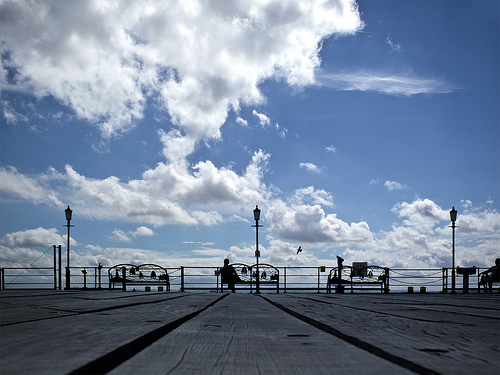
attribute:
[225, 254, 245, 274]
man — sitting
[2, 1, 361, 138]
cloud — big, bright, white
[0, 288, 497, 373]
floor — old, brown, wooden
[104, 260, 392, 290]
benches — spare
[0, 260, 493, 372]
dock — nice, big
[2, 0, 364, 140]
clouds — white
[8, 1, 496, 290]
sky — bright, clear, blue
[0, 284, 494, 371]
platform — wooden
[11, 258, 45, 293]
railing — pole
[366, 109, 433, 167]
sky — blue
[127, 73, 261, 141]
clouds — puffy, white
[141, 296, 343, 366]
boards — wooden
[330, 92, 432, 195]
sky — blue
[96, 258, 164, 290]
design — intricate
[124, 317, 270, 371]
planks — wood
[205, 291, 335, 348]
plank — wooden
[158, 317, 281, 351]
plank — wooden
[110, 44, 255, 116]
cloud — white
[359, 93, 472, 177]
sky — cloudless, blue